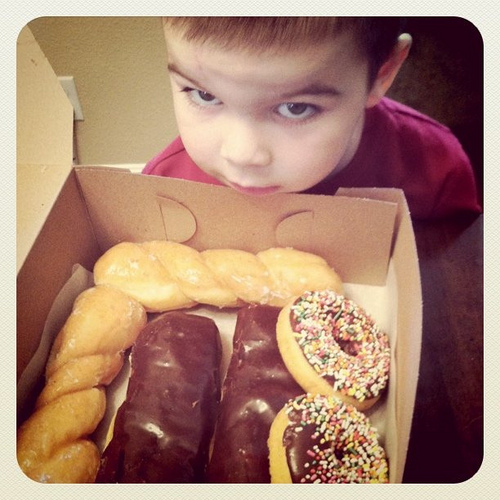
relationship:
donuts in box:
[30, 239, 399, 500] [14, 163, 419, 483]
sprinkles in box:
[289, 287, 406, 391] [14, 163, 419, 483]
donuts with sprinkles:
[265, 393, 399, 499] [289, 287, 406, 391]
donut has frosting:
[274, 289, 390, 412] [289, 287, 406, 391]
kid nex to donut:
[126, 18, 478, 261] [30, 239, 399, 500]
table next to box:
[419, 206, 481, 474] [14, 163, 419, 483]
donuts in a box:
[30, 239, 399, 500] [14, 163, 419, 483]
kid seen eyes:
[126, 18, 478, 261] [176, 84, 324, 123]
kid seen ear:
[126, 18, 478, 261] [364, 26, 414, 113]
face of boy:
[155, 19, 373, 199] [126, 18, 478, 261]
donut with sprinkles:
[274, 289, 390, 412] [289, 287, 406, 391]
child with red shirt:
[126, 18, 478, 261] [135, 101, 482, 223]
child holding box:
[126, 18, 478, 261] [14, 163, 419, 483]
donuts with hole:
[265, 393, 399, 499] [325, 312, 368, 469]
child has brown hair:
[126, 18, 478, 261] [157, 15, 401, 85]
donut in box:
[103, 304, 229, 485] [14, 163, 419, 483]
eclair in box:
[214, 301, 304, 483] [14, 163, 419, 483]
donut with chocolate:
[103, 304, 229, 485] [293, 300, 389, 395]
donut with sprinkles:
[103, 304, 229, 485] [299, 297, 377, 383]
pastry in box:
[90, 236, 347, 315] [14, 163, 419, 483]